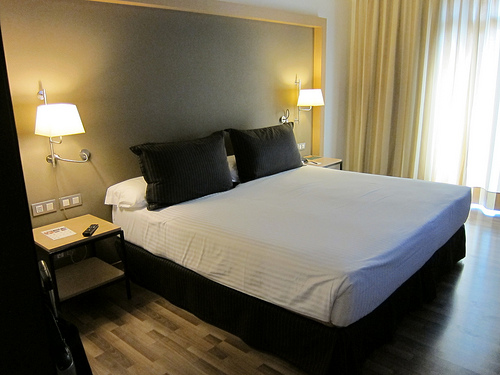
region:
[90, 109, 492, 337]
this is a bed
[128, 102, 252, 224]
this is a pillow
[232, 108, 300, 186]
this is a pillow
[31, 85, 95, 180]
this is a lamp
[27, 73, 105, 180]
this lights are on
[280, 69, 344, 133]
this is a lamp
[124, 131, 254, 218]
the pillow is black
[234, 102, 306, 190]
the pillow is black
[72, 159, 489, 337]
the bed cover is white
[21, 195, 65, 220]
this is a switch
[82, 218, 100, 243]
A remote control on the table.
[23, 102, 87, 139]
White lamp shade on the wall.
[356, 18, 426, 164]
Gold curtains on the window.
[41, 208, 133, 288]
Table next to the bed.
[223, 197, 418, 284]
White sheets on the bed.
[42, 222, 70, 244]
A paper on the table.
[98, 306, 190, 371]
The floor is wood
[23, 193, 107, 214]
An outlet on the wall.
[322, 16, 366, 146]
The wall is white.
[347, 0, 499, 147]
a hotel's cream colored curtains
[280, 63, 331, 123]
a lamp on a hotel wall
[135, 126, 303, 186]
black pillows on a hotel bed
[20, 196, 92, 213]
outlets on a wall of a hotel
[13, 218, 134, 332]
a nightstand made out of wood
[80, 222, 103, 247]
a remote control sitting on a table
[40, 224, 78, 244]
a paper sitting on a nightstand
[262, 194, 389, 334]
sheets that are fresh and white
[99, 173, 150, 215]
small white pillows on a bed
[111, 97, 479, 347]
the bed inside of a hotel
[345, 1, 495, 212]
bright light behind yellow draperies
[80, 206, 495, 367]
smooth dark brown floor of wood slats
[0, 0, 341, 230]
large tan headboard framed in blonde wood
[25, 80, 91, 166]
light fixture with white shade attached to wall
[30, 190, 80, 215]
panels with square electrical sockets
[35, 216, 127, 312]
bed table of shelves on open rack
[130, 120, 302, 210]
black upright pillows in front of white pillows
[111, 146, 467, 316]
large bed covered in white sheet with pale stripes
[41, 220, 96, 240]
remote control and piece of paper on table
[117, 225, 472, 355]
black bed skirt under mattress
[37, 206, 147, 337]
this is a bed side table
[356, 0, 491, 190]
this is a curtain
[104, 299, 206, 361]
the floor is wooden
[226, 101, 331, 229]
the pillow is black